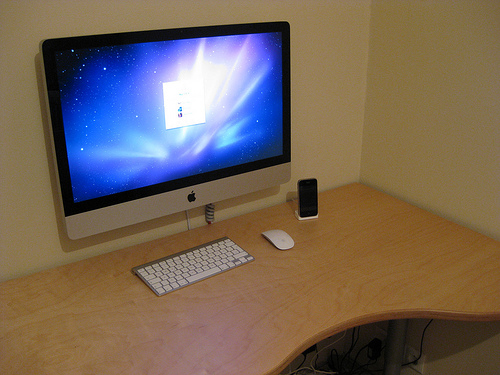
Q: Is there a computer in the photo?
A: Yes, there is a computer.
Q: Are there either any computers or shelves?
A: Yes, there is a computer.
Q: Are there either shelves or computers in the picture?
A: Yes, there is a computer.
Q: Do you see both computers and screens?
A: Yes, there are both a computer and a screen.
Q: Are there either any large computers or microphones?
A: Yes, there is a large computer.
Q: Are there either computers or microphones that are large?
A: Yes, the computer is large.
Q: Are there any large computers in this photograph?
A: Yes, there is a large computer.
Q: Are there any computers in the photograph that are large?
A: Yes, there is a computer that is large.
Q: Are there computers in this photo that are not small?
A: Yes, there is a large computer.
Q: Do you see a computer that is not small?
A: Yes, there is a large computer.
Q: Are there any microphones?
A: No, there are no microphones.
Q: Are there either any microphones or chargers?
A: No, there are no microphones or chargers.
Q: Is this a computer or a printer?
A: This is a computer.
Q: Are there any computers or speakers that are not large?
A: No, there is a computer but it is large.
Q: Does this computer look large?
A: Yes, the computer is large.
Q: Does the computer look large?
A: Yes, the computer is large.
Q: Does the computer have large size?
A: Yes, the computer is large.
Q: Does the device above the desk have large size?
A: Yes, the computer is large.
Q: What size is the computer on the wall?
A: The computer is large.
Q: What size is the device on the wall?
A: The computer is large.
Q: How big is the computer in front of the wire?
A: The computer is large.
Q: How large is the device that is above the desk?
A: The computer is large.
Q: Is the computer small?
A: No, the computer is large.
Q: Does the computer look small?
A: No, the computer is large.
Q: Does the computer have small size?
A: No, the computer is large.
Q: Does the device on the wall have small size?
A: No, the computer is large.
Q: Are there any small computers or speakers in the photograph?
A: No, there is a computer but it is large.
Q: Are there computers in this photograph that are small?
A: No, there is a computer but it is large.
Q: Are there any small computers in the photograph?
A: No, there is a computer but it is large.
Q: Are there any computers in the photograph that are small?
A: No, there is a computer but it is large.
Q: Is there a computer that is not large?
A: No, there is a computer but it is large.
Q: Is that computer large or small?
A: The computer is large.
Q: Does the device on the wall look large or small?
A: The computer is large.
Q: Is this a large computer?
A: Yes, this is a large computer.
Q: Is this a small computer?
A: No, this is a large computer.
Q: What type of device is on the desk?
A: The device is a computer.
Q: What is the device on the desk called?
A: The device is a computer.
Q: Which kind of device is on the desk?
A: The device is a computer.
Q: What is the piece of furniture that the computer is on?
A: The piece of furniture is a desk.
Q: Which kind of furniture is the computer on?
A: The computer is on the desk.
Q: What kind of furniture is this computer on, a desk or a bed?
A: The computer is on a desk.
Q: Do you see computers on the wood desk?
A: Yes, there is a computer on the desk.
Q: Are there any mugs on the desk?
A: No, there is a computer on the desk.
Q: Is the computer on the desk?
A: Yes, the computer is on the desk.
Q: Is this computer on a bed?
A: No, the computer is on the desk.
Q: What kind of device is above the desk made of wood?
A: The device is a computer.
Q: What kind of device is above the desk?
A: The device is a computer.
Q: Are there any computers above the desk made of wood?
A: Yes, there is a computer above the desk.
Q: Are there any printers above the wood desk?
A: No, there is a computer above the desk.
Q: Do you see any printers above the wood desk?
A: No, there is a computer above the desk.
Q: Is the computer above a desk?
A: Yes, the computer is above a desk.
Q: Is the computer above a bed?
A: No, the computer is above a desk.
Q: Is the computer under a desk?
A: No, the computer is above a desk.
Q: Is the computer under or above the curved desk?
A: The computer is above the desk.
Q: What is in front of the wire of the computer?
A: The computer is in front of the wire.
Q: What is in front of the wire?
A: The computer is in front of the wire.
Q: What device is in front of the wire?
A: The device is a computer.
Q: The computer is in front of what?
A: The computer is in front of the wire.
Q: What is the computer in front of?
A: The computer is in front of the wire.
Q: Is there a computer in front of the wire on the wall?
A: Yes, there is a computer in front of the wire.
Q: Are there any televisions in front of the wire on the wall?
A: No, there is a computer in front of the wire.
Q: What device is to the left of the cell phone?
A: The device is a computer.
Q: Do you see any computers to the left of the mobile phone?
A: Yes, there is a computer to the left of the mobile phone.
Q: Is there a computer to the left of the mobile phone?
A: Yes, there is a computer to the left of the mobile phone.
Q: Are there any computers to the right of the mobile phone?
A: No, the computer is to the left of the mobile phone.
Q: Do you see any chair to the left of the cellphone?
A: No, there is a computer to the left of the cellphone.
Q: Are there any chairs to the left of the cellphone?
A: No, there is a computer to the left of the cellphone.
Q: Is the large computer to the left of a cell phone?
A: Yes, the computer is to the left of a cell phone.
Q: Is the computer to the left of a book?
A: No, the computer is to the left of a cell phone.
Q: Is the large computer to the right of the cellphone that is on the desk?
A: No, the computer is to the left of the mobile phone.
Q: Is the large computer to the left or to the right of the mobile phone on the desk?
A: The computer is to the left of the cell phone.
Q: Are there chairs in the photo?
A: No, there are no chairs.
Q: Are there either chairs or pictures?
A: No, there are no chairs or pictures.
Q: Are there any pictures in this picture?
A: No, there are no pictures.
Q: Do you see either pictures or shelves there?
A: No, there are no pictures or shelves.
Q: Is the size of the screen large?
A: Yes, the screen is large.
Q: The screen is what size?
A: The screen is large.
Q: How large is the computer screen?
A: The screen is large.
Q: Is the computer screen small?
A: No, the screen is large.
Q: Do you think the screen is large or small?
A: The screen is large.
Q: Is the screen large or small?
A: The screen is large.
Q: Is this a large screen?
A: Yes, this is a large screen.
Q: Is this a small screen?
A: No, this is a large screen.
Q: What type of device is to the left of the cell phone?
A: The device is a screen.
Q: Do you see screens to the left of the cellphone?
A: Yes, there is a screen to the left of the cellphone.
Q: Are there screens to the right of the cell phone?
A: No, the screen is to the left of the cell phone.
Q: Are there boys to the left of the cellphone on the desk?
A: No, there is a screen to the left of the cell phone.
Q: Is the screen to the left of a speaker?
A: No, the screen is to the left of the cellphone.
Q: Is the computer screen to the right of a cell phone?
A: No, the screen is to the left of a cell phone.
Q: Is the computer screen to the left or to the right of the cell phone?
A: The screen is to the left of the cell phone.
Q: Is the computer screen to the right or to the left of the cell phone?
A: The screen is to the left of the cell phone.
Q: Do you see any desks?
A: Yes, there is a desk.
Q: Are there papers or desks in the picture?
A: Yes, there is a desk.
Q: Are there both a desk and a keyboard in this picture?
A: Yes, there are both a desk and a keyboard.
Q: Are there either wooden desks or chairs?
A: Yes, there is a wood desk.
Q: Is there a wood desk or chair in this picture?
A: Yes, there is a wood desk.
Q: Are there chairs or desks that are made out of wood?
A: Yes, the desk is made of wood.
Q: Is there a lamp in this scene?
A: No, there are no lamps.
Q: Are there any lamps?
A: No, there are no lamps.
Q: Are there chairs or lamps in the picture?
A: No, there are no lamps or chairs.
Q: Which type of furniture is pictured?
A: The furniture is a desk.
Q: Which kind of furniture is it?
A: The piece of furniture is a desk.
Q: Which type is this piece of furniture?
A: This is a desk.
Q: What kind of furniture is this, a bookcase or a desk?
A: This is a desk.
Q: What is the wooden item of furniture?
A: The piece of furniture is a desk.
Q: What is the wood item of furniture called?
A: The piece of furniture is a desk.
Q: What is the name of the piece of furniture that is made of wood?
A: The piece of furniture is a desk.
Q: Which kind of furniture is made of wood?
A: The furniture is a desk.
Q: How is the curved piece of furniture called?
A: The piece of furniture is a desk.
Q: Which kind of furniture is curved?
A: The furniture is a desk.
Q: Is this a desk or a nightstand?
A: This is a desk.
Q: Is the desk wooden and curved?
A: Yes, the desk is wooden and curved.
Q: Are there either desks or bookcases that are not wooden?
A: No, there is a desk but it is wooden.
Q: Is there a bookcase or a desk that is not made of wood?
A: No, there is a desk but it is made of wood.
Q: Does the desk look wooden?
A: Yes, the desk is wooden.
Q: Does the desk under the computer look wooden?
A: Yes, the desk is wooden.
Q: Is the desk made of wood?
A: Yes, the desk is made of wood.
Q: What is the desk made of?
A: The desk is made of wood.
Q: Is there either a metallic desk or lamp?
A: No, there is a desk but it is wooden.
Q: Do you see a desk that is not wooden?
A: No, there is a desk but it is wooden.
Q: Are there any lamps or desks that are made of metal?
A: No, there is a desk but it is made of wood.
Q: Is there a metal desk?
A: No, there is a desk but it is made of wood.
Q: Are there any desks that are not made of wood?
A: No, there is a desk but it is made of wood.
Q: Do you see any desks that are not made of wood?
A: No, there is a desk but it is made of wood.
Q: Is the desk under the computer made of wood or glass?
A: The desk is made of wood.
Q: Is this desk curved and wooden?
A: Yes, the desk is curved and wooden.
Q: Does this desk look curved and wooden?
A: Yes, the desk is curved and wooden.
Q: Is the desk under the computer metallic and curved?
A: No, the desk is curved but wooden.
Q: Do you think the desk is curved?
A: Yes, the desk is curved.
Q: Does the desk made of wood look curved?
A: Yes, the desk is curved.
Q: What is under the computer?
A: The desk is under the computer.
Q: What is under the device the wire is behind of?
A: The desk is under the computer.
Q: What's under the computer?
A: The desk is under the computer.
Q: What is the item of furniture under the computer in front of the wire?
A: The piece of furniture is a desk.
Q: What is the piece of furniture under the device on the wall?
A: The piece of furniture is a desk.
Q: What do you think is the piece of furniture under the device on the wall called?
A: The piece of furniture is a desk.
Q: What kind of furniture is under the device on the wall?
A: The piece of furniture is a desk.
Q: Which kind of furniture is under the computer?
A: The piece of furniture is a desk.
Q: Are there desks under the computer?
A: Yes, there is a desk under the computer.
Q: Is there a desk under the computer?
A: Yes, there is a desk under the computer.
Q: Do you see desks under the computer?
A: Yes, there is a desk under the computer.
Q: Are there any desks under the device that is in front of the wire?
A: Yes, there is a desk under the computer.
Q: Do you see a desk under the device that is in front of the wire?
A: Yes, there is a desk under the computer.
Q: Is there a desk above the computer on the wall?
A: No, the desk is under the computer.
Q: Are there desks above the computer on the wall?
A: No, the desk is under the computer.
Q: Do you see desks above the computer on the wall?
A: No, the desk is under the computer.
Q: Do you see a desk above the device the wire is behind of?
A: No, the desk is under the computer.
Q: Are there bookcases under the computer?
A: No, there is a desk under the computer.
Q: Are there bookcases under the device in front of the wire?
A: No, there is a desk under the computer.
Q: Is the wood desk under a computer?
A: Yes, the desk is under a computer.